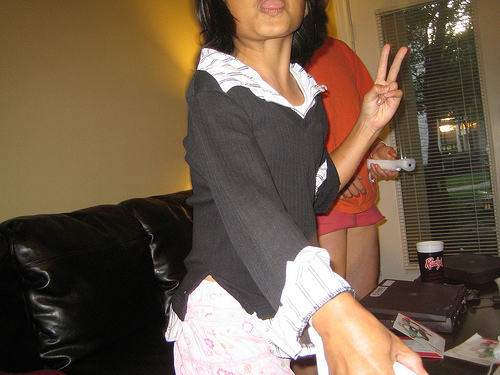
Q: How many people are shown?
A: Two.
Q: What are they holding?
A: Controllers.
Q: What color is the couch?
A: Black.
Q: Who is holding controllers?
A: The girls.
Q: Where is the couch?
A: Against the wall.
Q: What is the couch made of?
A: Leather.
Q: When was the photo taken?
A: Evening.